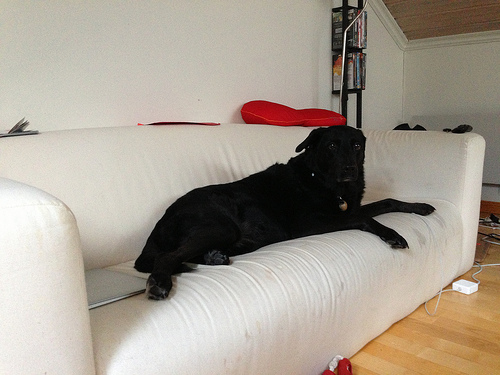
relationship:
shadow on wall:
[401, 101, 498, 205] [1, 3, 498, 183]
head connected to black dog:
[295, 123, 365, 190] [130, 124, 438, 302]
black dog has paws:
[130, 124, 438, 302] [377, 200, 416, 243]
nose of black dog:
[343, 164, 360, 174] [130, 124, 438, 302]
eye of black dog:
[326, 139, 348, 155] [130, 124, 438, 302]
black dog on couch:
[130, 124, 438, 302] [0, 122, 487, 374]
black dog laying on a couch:
[112, 120, 447, 306] [4, 126, 235, 181]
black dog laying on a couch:
[130, 124, 438, 302] [18, 104, 438, 340]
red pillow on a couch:
[238, 98, 348, 127] [0, 118, 488, 373]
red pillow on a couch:
[238, 87, 354, 137] [0, 122, 487, 374]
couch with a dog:
[25, 107, 413, 321] [161, 129, 381, 270]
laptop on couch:
[79, 257, 152, 312] [0, 135, 274, 373]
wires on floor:
[428, 260, 493, 318] [417, 308, 484, 371]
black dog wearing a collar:
[130, 124, 438, 302] [294, 152, 368, 210]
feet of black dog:
[151, 245, 231, 295] [130, 124, 438, 302]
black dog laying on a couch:
[130, 124, 438, 302] [16, 116, 484, 357]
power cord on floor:
[424, 230, 499, 330] [334, 224, 496, 372]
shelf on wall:
[326, 0, 376, 135] [4, 3, 409, 125]